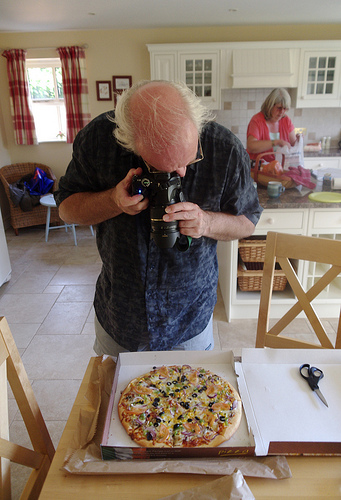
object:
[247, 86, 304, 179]
woman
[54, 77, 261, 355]
man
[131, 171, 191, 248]
camera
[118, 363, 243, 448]
pizza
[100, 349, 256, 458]
box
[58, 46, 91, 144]
curtains